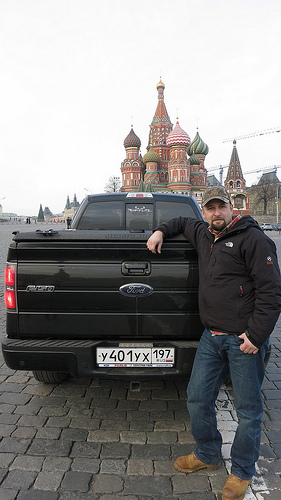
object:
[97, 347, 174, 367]
plate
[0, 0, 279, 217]
sky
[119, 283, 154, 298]
logo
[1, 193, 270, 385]
truck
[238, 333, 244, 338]
finger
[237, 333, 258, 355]
pocket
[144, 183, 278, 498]
man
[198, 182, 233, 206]
hat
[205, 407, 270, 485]
stones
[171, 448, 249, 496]
boots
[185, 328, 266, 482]
jeans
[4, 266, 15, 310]
red lights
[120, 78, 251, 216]
building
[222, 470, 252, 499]
shoes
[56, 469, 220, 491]
cobblestone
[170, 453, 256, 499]
work boots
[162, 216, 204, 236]
arm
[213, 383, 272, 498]
line